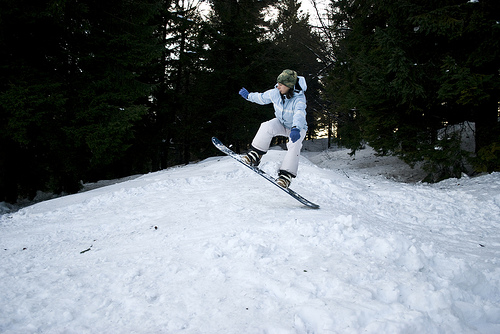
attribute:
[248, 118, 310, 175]
pants — white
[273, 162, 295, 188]
shoe — black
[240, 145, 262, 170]
shoe — black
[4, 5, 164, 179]
trees — green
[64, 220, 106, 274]
twigs — brown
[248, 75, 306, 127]
jacket — blue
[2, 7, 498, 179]
trees — green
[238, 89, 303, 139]
gloves — blue, dark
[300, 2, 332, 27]
cloudy sky — white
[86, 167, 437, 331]
snow — white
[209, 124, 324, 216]
snowboard — blue, black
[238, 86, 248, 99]
glove — blue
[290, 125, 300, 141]
glove — blue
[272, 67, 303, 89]
hat — green, beige, knit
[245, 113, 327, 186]
ski pants — white, down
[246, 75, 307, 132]
jacket — down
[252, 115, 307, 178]
pants — white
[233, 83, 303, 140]
gloves — blue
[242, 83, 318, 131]
coat — light blue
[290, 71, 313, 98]
hoodie — blue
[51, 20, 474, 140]
trees — evergreen